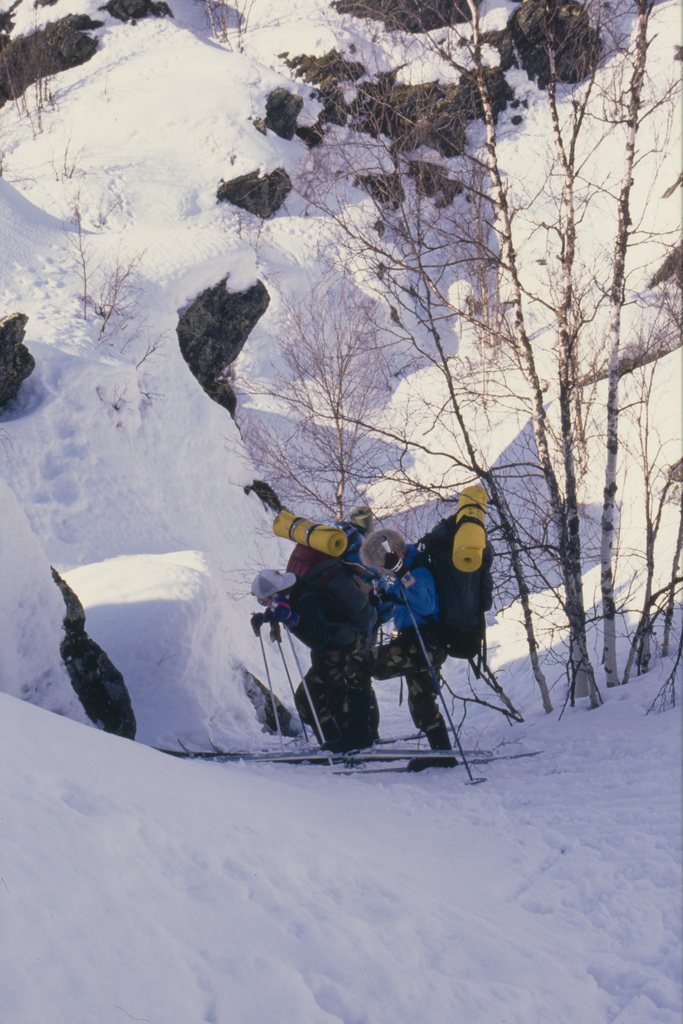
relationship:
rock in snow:
[171, 267, 276, 417] [3, 13, 682, 997]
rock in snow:
[54, 537, 303, 735] [3, 13, 682, 997]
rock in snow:
[9, 310, 40, 410] [3, 13, 682, 997]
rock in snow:
[234, 168, 294, 220] [3, 13, 682, 997]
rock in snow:
[8, 21, 677, 711] [362, 165, 404, 214]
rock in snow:
[268, 85, 457, 200] [231, 231, 384, 389]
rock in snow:
[175, 273, 269, 420] [120, 442, 246, 569]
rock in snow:
[503, 9, 639, 92] [527, 101, 646, 289]